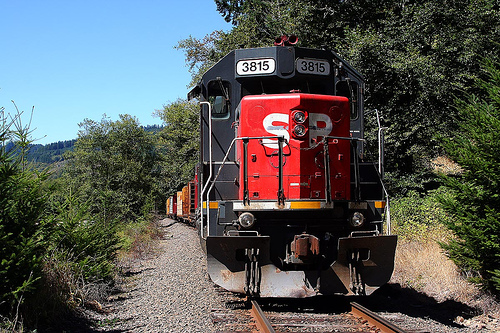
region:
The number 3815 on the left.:
[235, 59, 271, 74]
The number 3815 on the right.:
[295, 57, 332, 76]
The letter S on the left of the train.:
[250, 108, 295, 149]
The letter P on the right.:
[305, 108, 335, 145]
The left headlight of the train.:
[232, 205, 259, 229]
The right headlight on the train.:
[350, 209, 367, 227]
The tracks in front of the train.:
[245, 282, 391, 331]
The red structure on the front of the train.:
[235, 84, 348, 205]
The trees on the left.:
[1, 83, 158, 320]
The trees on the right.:
[237, 3, 490, 300]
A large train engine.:
[171, 43, 433, 310]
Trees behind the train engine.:
[57, 105, 186, 189]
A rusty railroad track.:
[242, 299, 392, 331]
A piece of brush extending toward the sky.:
[1, 99, 45, 163]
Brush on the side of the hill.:
[0, 155, 122, 290]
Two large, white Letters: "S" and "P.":
[253, 110, 343, 150]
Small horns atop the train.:
[270, 28, 300, 46]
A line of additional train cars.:
[154, 185, 199, 221]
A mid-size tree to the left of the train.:
[436, 55, 498, 285]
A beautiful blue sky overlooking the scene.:
[8, 14, 110, 82]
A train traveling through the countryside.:
[113, 28, 441, 330]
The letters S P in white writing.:
[255, 105, 337, 158]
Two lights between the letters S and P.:
[266, 107, 329, 143]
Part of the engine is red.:
[234, 90, 353, 213]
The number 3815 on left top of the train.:
[231, 51, 276, 78]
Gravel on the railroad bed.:
[113, 199, 470, 327]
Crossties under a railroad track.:
[165, 208, 435, 329]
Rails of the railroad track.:
[235, 283, 415, 331]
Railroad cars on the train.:
[160, 180, 205, 232]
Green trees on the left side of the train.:
[210, 5, 498, 255]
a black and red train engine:
[190, 34, 400, 304]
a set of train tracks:
[243, 294, 405, 331]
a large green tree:
[432, 83, 498, 297]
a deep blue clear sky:
[1, 1, 236, 142]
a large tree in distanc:
[71, 116, 155, 215]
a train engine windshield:
[242, 76, 334, 95]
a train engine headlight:
[237, 210, 255, 230]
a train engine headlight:
[350, 210, 365, 227]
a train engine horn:
[273, 31, 299, 46]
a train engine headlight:
[293, 110, 306, 124]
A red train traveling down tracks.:
[189, 28, 418, 299]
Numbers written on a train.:
[230, 47, 288, 82]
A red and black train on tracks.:
[156, 48, 411, 326]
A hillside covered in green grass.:
[0, 105, 207, 328]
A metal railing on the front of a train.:
[238, 117, 359, 230]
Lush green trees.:
[151, 1, 496, 303]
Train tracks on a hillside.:
[118, 197, 431, 329]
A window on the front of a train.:
[205, 87, 241, 132]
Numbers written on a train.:
[230, 87, 350, 174]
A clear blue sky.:
[0, 0, 237, 149]